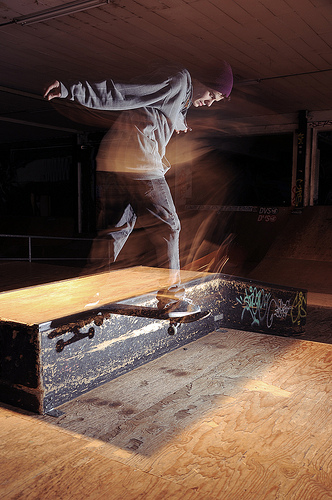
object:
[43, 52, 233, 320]
boy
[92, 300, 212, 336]
skateboard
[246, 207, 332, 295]
ramp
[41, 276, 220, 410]
side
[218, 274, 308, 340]
side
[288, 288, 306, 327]
graffiti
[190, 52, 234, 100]
beanie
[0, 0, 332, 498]
image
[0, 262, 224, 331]
deck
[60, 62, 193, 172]
sweater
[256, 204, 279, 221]
stickers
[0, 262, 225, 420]
beam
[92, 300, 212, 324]
support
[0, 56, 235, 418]
exposure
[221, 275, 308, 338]
portion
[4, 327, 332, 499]
floor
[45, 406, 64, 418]
bracket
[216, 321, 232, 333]
bracket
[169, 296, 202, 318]
shoes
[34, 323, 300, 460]
shadow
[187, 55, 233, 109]
head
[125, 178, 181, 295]
leg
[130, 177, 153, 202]
pocket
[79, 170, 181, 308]
pants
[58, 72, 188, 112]
arm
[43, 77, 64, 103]
hand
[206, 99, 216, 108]
nose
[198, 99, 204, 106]
mouth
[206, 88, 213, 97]
eye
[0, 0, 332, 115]
roof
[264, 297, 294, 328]
writing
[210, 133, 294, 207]
door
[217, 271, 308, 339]
board